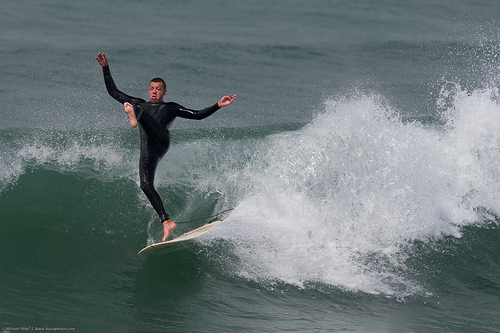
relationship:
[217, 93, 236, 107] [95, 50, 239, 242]
hand of man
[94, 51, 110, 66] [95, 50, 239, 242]
hand of man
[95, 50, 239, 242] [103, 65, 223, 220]
man wearing wetsuit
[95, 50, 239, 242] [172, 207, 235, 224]
man attached to rope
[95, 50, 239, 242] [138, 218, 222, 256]
man on surfboard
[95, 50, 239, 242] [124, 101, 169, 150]
man has leg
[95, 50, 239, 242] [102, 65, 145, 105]
man has arm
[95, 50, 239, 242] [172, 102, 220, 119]
man has arm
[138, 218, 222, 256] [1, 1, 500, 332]
surfboard in water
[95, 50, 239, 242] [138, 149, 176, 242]
man has left leg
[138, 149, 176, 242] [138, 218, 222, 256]
left leg on surfboard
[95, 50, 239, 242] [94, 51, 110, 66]
man has hand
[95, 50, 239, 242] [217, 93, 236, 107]
man has hand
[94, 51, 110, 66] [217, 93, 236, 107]
hand apart from hand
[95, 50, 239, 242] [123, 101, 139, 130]
man has right foot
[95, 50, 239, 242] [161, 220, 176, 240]
man has left foot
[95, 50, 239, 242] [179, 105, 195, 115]
man has left bicep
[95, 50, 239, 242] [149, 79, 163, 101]
man has face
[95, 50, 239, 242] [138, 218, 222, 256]
man riding surfboard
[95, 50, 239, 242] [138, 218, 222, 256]
man falling off surfboard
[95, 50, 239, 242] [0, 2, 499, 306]
man riding wave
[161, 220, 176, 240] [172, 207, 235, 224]
left foot attached to rope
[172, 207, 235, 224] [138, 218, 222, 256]
rope attached to surfboard